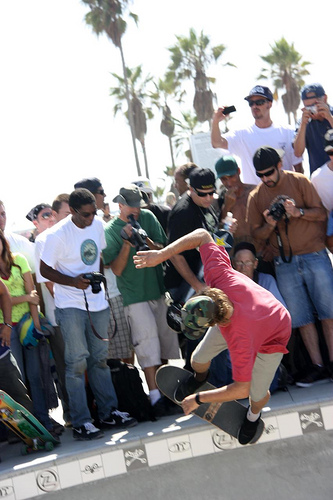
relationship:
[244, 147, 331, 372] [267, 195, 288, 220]
man holding camera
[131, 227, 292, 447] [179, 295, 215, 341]
skateboarder wearing camouflage hat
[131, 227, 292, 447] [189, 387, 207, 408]
skateboarder wearing watch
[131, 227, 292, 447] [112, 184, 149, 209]
skateboarder wearing hat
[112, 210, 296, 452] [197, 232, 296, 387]
skateboarder wearing shirt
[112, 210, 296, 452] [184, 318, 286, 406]
skateboarder wearing shorts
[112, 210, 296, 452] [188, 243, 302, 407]
skateboarder wearing outfit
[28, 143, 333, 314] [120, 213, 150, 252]
spectators have camera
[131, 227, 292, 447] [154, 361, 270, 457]
skateboarder on skateboard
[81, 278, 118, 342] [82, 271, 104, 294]
strap dangling from a camera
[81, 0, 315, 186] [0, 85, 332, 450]
trees tower over crowd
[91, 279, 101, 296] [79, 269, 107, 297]
extended lens on camera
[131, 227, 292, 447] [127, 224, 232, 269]
skateboarder with arm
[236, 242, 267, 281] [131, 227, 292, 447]
man crouched behind skateboarder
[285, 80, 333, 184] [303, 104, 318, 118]
man holding camera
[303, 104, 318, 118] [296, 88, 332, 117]
camera to face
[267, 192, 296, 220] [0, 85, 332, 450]
camera used by crowd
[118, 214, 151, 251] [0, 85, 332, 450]
camera used by crowd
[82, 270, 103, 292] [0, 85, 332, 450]
camera used by crowd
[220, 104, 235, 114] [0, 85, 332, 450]
camera used by crowd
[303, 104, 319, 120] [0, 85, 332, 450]
camera used by crowd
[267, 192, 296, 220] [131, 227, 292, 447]
camera records skateboarder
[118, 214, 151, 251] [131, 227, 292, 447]
camera records skateboarder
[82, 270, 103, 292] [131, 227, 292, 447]
camera records skateboarder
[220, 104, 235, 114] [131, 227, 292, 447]
camera records skateboarder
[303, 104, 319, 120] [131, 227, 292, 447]
camera records skateboarder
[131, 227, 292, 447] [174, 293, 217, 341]
skateboarder wears camouflage hat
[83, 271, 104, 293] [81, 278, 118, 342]
camera has strap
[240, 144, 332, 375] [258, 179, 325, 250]
man has chest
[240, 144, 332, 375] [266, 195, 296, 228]
man holds camera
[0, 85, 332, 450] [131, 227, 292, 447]
crowd watches skateboarder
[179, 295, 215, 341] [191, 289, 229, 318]
camouflage hat covers head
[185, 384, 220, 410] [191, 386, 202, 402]
wrist has band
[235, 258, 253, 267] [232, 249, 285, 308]
glasses worn by man